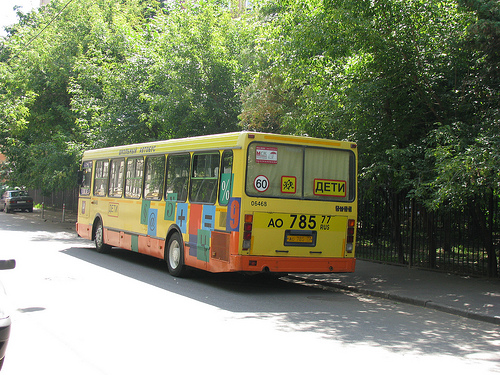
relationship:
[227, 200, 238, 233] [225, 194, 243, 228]
9 on blue background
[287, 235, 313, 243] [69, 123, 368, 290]
license plate on back of bus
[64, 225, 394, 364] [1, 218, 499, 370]
shadow on ground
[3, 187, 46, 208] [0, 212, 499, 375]
car in road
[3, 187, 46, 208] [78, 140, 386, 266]
car in front of bus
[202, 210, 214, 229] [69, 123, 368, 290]
equal sign on bus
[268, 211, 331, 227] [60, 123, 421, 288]
ao78577rus on bus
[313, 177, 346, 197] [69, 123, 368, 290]
sign on bus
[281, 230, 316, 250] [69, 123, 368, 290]
license plate on bus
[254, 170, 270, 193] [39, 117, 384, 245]
sign on bus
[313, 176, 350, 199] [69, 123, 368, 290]
sign on bus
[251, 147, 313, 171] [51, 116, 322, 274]
sign on bus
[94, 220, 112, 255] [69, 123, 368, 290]
tire on bus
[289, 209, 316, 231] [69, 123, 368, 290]
785 on bus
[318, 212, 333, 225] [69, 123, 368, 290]
number 77 on bus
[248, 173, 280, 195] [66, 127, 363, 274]
60 on bus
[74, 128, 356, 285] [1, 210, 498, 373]
bus on side of road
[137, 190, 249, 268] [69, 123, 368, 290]
signs on bus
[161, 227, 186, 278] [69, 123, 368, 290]
tire on bus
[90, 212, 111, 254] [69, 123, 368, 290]
tire on bus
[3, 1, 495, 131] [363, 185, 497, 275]
trees behind fence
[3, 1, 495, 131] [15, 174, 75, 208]
trees behind fence